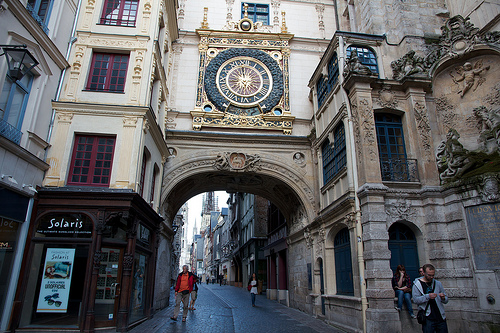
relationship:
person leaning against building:
[393, 264, 417, 319] [53, 31, 473, 318]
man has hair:
[411, 264, 447, 333] [423, 266, 435, 267]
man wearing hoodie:
[413, 265, 450, 332] [410, 277, 447, 319]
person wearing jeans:
[247, 271, 260, 307] [248, 292, 258, 307]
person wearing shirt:
[247, 273, 258, 306] [244, 278, 256, 300]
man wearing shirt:
[170, 265, 197, 322] [174, 272, 194, 296]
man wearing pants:
[170, 265, 197, 322] [164, 290, 192, 321]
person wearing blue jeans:
[391, 262, 416, 324] [395, 291, 415, 323]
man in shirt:
[172, 265, 196, 328] [179, 273, 189, 292]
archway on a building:
[162, 129, 320, 232] [37, 2, 499, 327]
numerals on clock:
[217, 55, 271, 102] [218, 54, 276, 105]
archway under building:
[154, 129, 321, 314] [149, 37, 491, 247]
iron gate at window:
[379, 153, 422, 188] [374, 104, 422, 189]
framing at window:
[88, 150, 95, 157] [51, 124, 106, 176]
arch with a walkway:
[163, 137, 322, 229] [163, 172, 348, 329]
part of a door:
[400, 239, 410, 251] [385, 215, 421, 290]